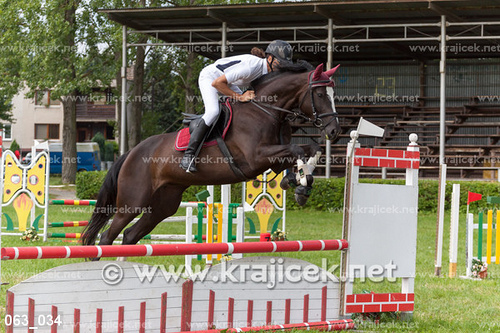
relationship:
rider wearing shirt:
[178, 40, 294, 172] [214, 47, 267, 87]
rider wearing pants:
[178, 40, 294, 172] [190, 62, 245, 127]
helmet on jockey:
[261, 28, 308, 74] [145, 28, 299, 173]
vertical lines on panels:
[11, 272, 353, 331] [2, 238, 355, 330]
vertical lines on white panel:
[11, 272, 353, 331] [341, 181, 432, 288]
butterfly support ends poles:
[231, 173, 300, 241] [35, 157, 498, 309]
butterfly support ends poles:
[4, 140, 58, 240] [35, 157, 498, 309]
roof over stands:
[97, 1, 494, 79] [279, 94, 499, 179]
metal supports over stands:
[112, 6, 497, 171] [279, 94, 499, 179]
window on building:
[34, 122, 59, 142] [2, 58, 74, 160]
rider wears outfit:
[81, 32, 353, 246] [185, 48, 261, 126]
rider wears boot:
[81, 32, 353, 246] [176, 124, 210, 178]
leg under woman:
[184, 64, 242, 162] [172, 37, 296, 150]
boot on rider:
[179, 117, 209, 172] [183, 38, 295, 168]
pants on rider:
[178, 66, 240, 145] [180, 33, 290, 165]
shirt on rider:
[209, 44, 270, 90] [183, 38, 295, 168]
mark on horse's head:
[325, 84, 341, 126] [295, 55, 344, 142]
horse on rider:
[55, 52, 349, 249] [169, 27, 304, 186]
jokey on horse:
[178, 38, 295, 173] [76, 60, 342, 260]